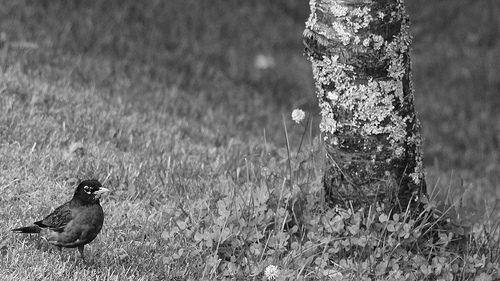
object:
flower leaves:
[218, 210, 233, 216]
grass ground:
[0, 0, 498, 279]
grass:
[1, 1, 484, 278]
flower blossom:
[289, 107, 307, 124]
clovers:
[396, 224, 416, 241]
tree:
[300, 0, 430, 233]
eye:
[84, 185, 92, 194]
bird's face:
[79, 179, 111, 197]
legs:
[76, 246, 86, 258]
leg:
[57, 247, 67, 264]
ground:
[2, 0, 499, 280]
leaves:
[473, 272, 494, 280]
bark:
[300, 0, 430, 222]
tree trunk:
[299, 0, 438, 241]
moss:
[329, 7, 347, 18]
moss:
[391, 148, 405, 157]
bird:
[10, 180, 109, 266]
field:
[0, 0, 500, 280]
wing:
[33, 210, 75, 227]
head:
[72, 177, 107, 202]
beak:
[94, 186, 109, 195]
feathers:
[14, 224, 45, 230]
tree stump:
[302, 0, 440, 237]